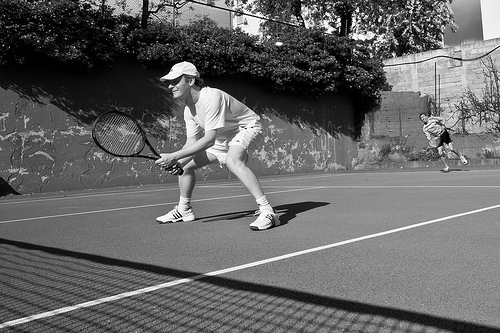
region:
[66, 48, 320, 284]
a person playing tennis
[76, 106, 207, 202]
a tennis racket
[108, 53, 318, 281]
someone wearing athletic sneakers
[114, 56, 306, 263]
someone wearing socks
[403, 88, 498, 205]
someone running on a tennis court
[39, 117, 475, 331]
a tennis court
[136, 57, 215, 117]
someone wearing a hat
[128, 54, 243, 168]
someone wearing a tshirt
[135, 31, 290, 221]
someone wearing shorts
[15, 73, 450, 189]
cement wall on a tennis court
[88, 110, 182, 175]
A black tennis racket.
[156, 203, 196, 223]
White and black tennis shoe on a man's right foot.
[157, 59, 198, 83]
A white hat on a man with a black racket.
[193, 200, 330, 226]
Black shadow of a man leaning over with a racket.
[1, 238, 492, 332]
Black shadow of a net on the court.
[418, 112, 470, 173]
A man in black shorts and a striped shirt in the background.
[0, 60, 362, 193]
A long peeling concrete wall with bush shadow on it.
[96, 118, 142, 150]
White strings on a black racket.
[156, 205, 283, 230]
White and black tennis shoes on a man with a black racket.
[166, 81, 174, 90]
Nose on the face of the man wearing a hat.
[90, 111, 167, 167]
a metal tennis racket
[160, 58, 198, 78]
a baseball cap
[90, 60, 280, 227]
a man holding a tennis racket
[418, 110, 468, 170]
a man playing tennis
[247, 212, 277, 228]
a man's left shoe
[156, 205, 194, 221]
a man's right shoe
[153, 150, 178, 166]
a man's left hand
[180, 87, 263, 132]
a man's white shirt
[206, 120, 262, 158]
a man's tennis shorts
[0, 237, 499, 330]
shadow of a tennis net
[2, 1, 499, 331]
Black and white image of men playing tennis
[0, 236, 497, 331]
Shadow of a tennis net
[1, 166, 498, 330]
Tennis court with white lines painted on it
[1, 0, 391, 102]
Bushes hanging over a wall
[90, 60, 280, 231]
Man in white squatting on a tennis court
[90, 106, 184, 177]
Black tennis racket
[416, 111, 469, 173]
Man in a striped shirt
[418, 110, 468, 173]
Man with one foot of the ground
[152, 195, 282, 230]
White socks in white sneakers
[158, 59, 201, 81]
White baseball cap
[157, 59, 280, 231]
tennis player in his tennis stance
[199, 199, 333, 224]
tennis player's shadow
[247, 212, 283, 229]
Adidas tennis shoes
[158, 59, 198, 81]
tennis cap to keep sun from eyes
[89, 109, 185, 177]
tennis racquet for tennis game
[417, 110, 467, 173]
tennis player's teammate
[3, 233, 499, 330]
tennis player court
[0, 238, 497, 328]
tennis net shadow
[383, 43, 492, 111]
wall to keep tennis games private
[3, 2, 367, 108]
bushes to make tennis court look fancy